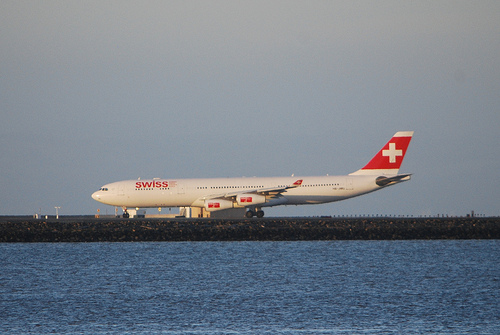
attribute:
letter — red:
[122, 170, 185, 194]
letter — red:
[135, 170, 172, 194]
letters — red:
[116, 167, 194, 190]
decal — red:
[184, 194, 230, 221]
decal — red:
[230, 185, 289, 215]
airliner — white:
[65, 117, 440, 226]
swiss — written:
[122, 175, 211, 204]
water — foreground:
[48, 243, 308, 326]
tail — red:
[349, 131, 437, 192]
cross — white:
[377, 144, 428, 174]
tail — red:
[357, 120, 474, 203]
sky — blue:
[9, 24, 309, 174]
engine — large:
[226, 186, 283, 210]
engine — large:
[181, 188, 253, 232]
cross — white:
[374, 135, 411, 172]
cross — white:
[380, 139, 405, 163]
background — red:
[377, 104, 422, 179]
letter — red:
[129, 180, 142, 192]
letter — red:
[136, 175, 148, 186]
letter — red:
[142, 179, 162, 193]